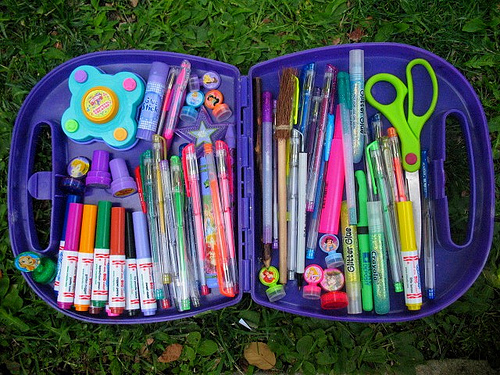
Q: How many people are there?
A: 0.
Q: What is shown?
A: Art supplies.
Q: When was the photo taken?
A: Afternoon.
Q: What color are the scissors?
A: Green.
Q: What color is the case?
A: Blue.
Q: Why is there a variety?
A: Colors.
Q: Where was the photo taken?
A: In the grass.